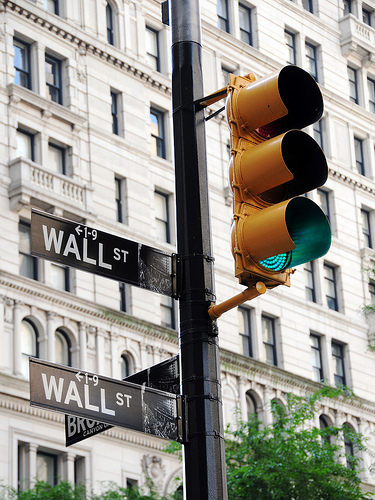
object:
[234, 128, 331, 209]
stop light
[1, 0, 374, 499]
building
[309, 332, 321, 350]
window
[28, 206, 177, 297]
sign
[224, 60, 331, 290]
traffic light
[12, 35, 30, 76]
window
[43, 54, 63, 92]
window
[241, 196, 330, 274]
light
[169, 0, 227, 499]
pole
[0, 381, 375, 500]
shrubs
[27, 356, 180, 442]
sign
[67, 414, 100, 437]
word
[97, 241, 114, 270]
letter